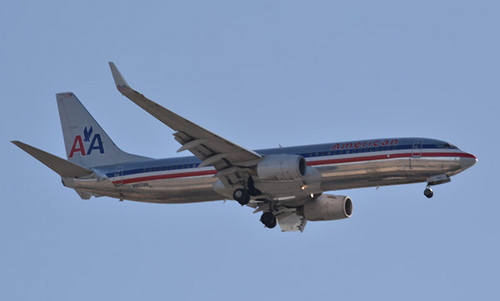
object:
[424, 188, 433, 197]
front wheel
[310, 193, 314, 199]
lights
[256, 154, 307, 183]
engine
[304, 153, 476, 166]
stripes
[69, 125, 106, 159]
logo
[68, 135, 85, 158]
letter a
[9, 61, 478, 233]
airplane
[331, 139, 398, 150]
american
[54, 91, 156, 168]
tail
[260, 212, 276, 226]
wheel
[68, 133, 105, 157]
lettering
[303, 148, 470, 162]
stripes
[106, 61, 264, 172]
wing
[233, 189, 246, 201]
wheel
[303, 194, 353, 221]
engine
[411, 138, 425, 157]
door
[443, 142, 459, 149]
cockpit